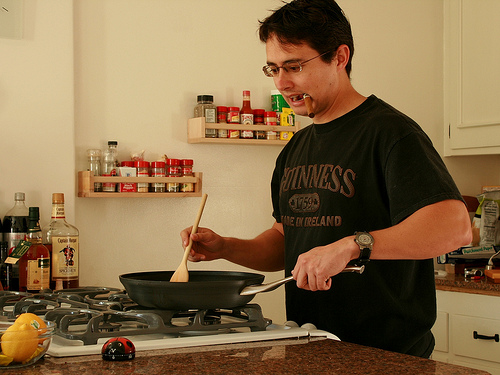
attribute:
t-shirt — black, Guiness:
[262, 92, 471, 353]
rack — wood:
[82, 151, 212, 209]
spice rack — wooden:
[186, 118, 300, 152]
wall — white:
[1, 0, 499, 325]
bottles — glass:
[19, 192, 78, 290]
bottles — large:
[1, 183, 77, 205]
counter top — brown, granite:
[260, 324, 450, 374]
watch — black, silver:
[351, 229, 376, 267]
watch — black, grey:
[352, 230, 374, 265]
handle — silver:
[238, 236, 364, 315]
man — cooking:
[178, 1, 478, 363]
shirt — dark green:
[264, 93, 466, 358]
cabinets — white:
[429, 10, 499, 147]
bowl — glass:
[0, 308, 55, 369]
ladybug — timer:
[100, 337, 135, 362]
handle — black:
[467, 329, 499, 347]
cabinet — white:
[448, 312, 498, 366]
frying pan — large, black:
[132, 255, 359, 329]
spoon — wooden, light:
[165, 183, 220, 284]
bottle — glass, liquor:
[46, 194, 96, 294]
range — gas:
[83, 293, 323, 344]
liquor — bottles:
[23, 190, 92, 290]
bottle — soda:
[6, 183, 36, 291]